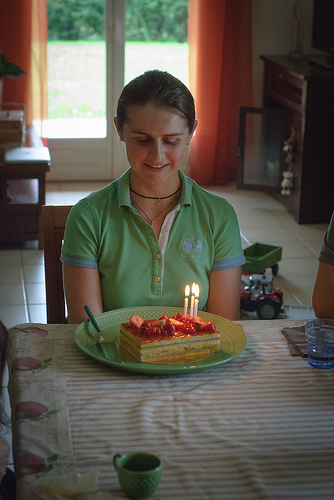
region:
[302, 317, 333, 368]
a small blue glass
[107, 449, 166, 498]
a green coffee mug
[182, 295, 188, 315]
a small white candle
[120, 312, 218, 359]
a large slice of cake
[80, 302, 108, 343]
green silverware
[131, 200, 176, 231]
a girl's necklace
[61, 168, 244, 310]
a green short sleeve shirt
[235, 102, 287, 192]
a cabinet door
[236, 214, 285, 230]
a piece of white floor tile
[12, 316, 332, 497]
a white and pink tablecloth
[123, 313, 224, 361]
a delicious strawberry cake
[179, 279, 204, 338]
three candles on a cake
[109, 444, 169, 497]
a small green teacup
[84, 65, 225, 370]
a women enjoying her cake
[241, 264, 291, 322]
a red toy truck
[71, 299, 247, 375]
a plate with cake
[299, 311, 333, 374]
a clear blue glass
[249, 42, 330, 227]
a brown cabinet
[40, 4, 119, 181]
the backyard behind glass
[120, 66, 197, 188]
a brunnete smiling woman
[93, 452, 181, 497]
green coffee cup on table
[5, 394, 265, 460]
striped table cloth on table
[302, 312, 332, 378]
blue drinking glass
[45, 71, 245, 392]
woman with birthday cake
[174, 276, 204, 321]
candles on birthday cake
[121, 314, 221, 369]
strawberries on a cake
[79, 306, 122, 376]
cake cutter on green plate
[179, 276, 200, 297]
flame on candles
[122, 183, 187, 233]
necklaces around woman's neck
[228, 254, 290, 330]
child's toy truck on floor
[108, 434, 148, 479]
a teacup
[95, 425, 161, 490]
a teacup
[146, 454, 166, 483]
a teacup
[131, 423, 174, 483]
a teacup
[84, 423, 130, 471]
a teacup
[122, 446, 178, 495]
a teacup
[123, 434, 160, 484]
a teacup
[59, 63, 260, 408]
a woman getting ready to eat birthday cake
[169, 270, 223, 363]
candles on a cake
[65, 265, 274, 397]
cake on a plate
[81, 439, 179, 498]
a cup on a table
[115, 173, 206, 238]
necklace on a woman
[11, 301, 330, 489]
a tablecloth on a table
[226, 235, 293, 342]
toys on the floor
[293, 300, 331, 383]
a glass on a table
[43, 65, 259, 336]
a woman wearing a green shirt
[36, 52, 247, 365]
a woman sitting in a chair